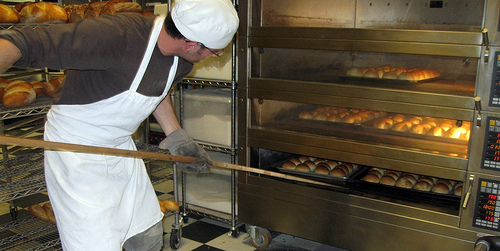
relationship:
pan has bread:
[288, 56, 428, 104] [326, 47, 447, 92]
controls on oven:
[471, 175, 499, 230] [246, 144, 498, 229]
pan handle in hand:
[0, 135, 349, 191] [160, 131, 215, 176]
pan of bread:
[246, 0, 498, 249] [366, 163, 465, 196]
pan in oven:
[246, 0, 498, 249] [356, 178, 458, 208]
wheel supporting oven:
[245, 225, 267, 249] [213, 93, 496, 243]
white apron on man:
[38, 16, 179, 248] [0, 0, 240, 251]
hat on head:
[169, 1, 239, 51] [164, 0, 238, 63]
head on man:
[164, 0, 238, 63] [0, 0, 240, 251]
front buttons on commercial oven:
[473, 173, 498, 234] [167, 3, 498, 249]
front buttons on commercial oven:
[480, 116, 499, 177] [167, 3, 498, 249]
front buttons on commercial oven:
[494, 165, 499, 168] [167, 3, 498, 249]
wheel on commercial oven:
[248, 225, 267, 250] [236, 0, 500, 251]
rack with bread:
[0, 0, 183, 250] [372, 111, 472, 142]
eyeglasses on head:
[185, 37, 227, 64] [164, 0, 238, 63]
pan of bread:
[279, 152, 359, 189] [306, 151, 358, 188]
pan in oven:
[279, 152, 359, 189] [161, 0, 484, 245]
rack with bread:
[0, 0, 183, 250] [1, 2, 19, 21]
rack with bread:
[0, 0, 183, 250] [21, 2, 68, 23]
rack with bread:
[0, 0, 183, 250] [2, 79, 38, 108]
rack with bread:
[0, 0, 183, 250] [42, 71, 65, 95]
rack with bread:
[0, 0, 183, 250] [66, 2, 85, 22]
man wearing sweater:
[0, 0, 240, 251] [11, 27, 215, 99]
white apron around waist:
[42, 15, 179, 251] [33, 89, 154, 168]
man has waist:
[0, 0, 240, 251] [33, 89, 154, 168]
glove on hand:
[157, 126, 214, 178] [155, 127, 215, 177]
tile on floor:
[179, 218, 229, 242] [161, 210, 337, 250]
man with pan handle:
[13, 4, 248, 238] [0, 135, 349, 191]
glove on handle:
[161, 126, 231, 191] [191, 132, 348, 217]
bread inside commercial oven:
[364, 174, 382, 184] [236, 0, 500, 251]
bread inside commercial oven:
[326, 169, 344, 178] [236, 0, 500, 251]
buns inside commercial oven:
[342, 57, 441, 88] [236, 0, 500, 251]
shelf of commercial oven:
[261, 68, 477, 110] [236, 0, 500, 251]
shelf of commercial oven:
[251, 47, 477, 99] [236, 0, 500, 251]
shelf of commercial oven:
[257, 1, 484, 31] [236, 0, 500, 251]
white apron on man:
[42, 15, 179, 251] [0, 0, 240, 251]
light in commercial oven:
[435, 118, 472, 144] [236, 0, 500, 251]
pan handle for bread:
[3, 122, 337, 197] [326, 169, 344, 178]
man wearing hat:
[0, 0, 240, 251] [169, 0, 239, 51]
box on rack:
[171, 87, 236, 148] [171, 39, 244, 239]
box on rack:
[172, 146, 241, 218] [171, 39, 244, 239]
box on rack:
[186, 42, 240, 84] [171, 39, 244, 239]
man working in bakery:
[0, 0, 240, 251] [184, 2, 498, 249]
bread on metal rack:
[387, 115, 457, 147] [261, 128, 447, 160]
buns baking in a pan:
[380, 177, 396, 187] [260, 157, 460, 216]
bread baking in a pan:
[295, 102, 476, 138] [320, 75, 442, 85]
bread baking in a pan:
[277, 155, 469, 198] [268, 110, 465, 156]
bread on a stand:
[294, 154, 351, 182] [247, 198, 442, 249]